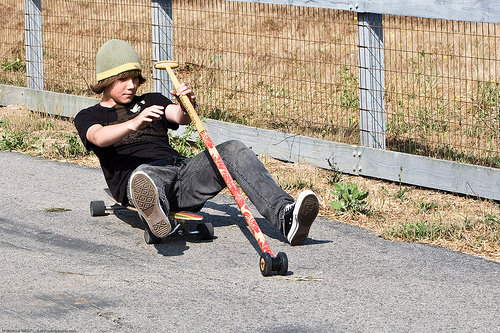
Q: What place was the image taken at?
A: It was taken at the pavement.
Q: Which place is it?
A: It is a pavement.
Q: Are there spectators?
A: No, there are no spectators.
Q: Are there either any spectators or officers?
A: No, there are no spectators or officers.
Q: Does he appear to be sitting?
A: Yes, the guy is sitting.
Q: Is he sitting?
A: Yes, the guy is sitting.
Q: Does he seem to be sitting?
A: Yes, the guy is sitting.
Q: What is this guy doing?
A: The guy is sitting.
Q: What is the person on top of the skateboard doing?
A: The guy is sitting.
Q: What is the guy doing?
A: The guy is sitting.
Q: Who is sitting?
A: The guy is sitting.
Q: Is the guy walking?
A: No, the guy is sitting.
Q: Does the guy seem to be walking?
A: No, the guy is sitting.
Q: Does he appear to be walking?
A: No, the guy is sitting.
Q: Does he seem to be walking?
A: No, the guy is sitting.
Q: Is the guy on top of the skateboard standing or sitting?
A: The guy is sitting.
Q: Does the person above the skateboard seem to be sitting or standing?
A: The guy is sitting.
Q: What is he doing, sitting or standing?
A: The guy is sitting.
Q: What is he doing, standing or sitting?
A: The guy is sitting.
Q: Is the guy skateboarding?
A: Yes, the guy is skateboarding.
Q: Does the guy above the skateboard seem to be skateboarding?
A: Yes, the guy is skateboarding.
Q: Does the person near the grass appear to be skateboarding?
A: Yes, the guy is skateboarding.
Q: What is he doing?
A: The guy is skateboarding.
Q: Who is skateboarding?
A: The guy is skateboarding.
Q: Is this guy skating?
A: No, the guy is skateboarding.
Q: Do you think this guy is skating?
A: No, the guy is skateboarding.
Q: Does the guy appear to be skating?
A: No, the guy is skateboarding.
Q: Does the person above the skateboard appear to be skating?
A: No, the guy is skateboarding.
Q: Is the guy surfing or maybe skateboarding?
A: The guy is skateboarding.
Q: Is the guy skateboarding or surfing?
A: The guy is skateboarding.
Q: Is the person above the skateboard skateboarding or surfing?
A: The guy is skateboarding.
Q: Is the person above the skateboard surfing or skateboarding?
A: The guy is skateboarding.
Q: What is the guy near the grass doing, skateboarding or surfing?
A: The guy is skateboarding.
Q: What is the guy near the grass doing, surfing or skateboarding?
A: The guy is skateboarding.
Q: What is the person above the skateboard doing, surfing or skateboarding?
A: The guy is skateboarding.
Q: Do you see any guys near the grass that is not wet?
A: Yes, there is a guy near the grass.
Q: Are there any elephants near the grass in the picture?
A: No, there is a guy near the grass.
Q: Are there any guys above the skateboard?
A: Yes, there is a guy above the skateboard.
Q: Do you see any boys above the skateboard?
A: No, there is a guy above the skateboard.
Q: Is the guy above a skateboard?
A: Yes, the guy is above a skateboard.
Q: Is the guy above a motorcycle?
A: No, the guy is above a skateboard.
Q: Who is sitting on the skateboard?
A: The guy is sitting on the skateboard.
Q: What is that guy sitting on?
A: The guy is sitting on the skateboard.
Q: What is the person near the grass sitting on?
A: The guy is sitting on the skateboard.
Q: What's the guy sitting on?
A: The guy is sitting on the skateboard.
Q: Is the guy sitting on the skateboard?
A: Yes, the guy is sitting on the skateboard.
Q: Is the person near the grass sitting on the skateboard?
A: Yes, the guy is sitting on the skateboard.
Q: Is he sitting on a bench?
A: No, the guy is sitting on the skateboard.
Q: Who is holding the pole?
A: The guy is holding the pole.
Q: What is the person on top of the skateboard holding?
A: The guy is holding the pole.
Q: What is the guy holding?
A: The guy is holding the pole.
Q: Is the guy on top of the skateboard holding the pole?
A: Yes, the guy is holding the pole.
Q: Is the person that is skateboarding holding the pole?
A: Yes, the guy is holding the pole.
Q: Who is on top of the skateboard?
A: The guy is on top of the skateboard.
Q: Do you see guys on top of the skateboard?
A: Yes, there is a guy on top of the skateboard.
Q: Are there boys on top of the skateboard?
A: No, there is a guy on top of the skateboard.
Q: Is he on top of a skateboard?
A: Yes, the guy is on top of a skateboard.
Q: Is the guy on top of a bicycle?
A: No, the guy is on top of a skateboard.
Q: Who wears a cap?
A: The guy wears a cap.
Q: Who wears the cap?
A: The guy wears a cap.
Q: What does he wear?
A: The guy wears a cap.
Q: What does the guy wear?
A: The guy wears a cap.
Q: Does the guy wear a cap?
A: Yes, the guy wears a cap.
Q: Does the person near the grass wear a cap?
A: Yes, the guy wears a cap.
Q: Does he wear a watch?
A: No, the guy wears a cap.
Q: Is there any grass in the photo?
A: Yes, there is grass.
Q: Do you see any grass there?
A: Yes, there is grass.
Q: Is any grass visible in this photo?
A: Yes, there is grass.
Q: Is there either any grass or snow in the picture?
A: Yes, there is grass.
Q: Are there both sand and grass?
A: No, there is grass but no sand.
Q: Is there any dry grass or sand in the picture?
A: Yes, there is dry grass.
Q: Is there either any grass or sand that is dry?
A: Yes, the grass is dry.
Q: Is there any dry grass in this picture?
A: Yes, there is dry grass.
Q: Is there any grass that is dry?
A: Yes, there is grass that is dry.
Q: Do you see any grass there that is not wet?
A: Yes, there is dry grass.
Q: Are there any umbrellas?
A: No, there are no umbrellas.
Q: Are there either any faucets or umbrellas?
A: No, there are no umbrellas or faucets.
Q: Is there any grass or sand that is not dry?
A: No, there is grass but it is dry.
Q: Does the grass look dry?
A: Yes, the grass is dry.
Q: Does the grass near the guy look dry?
A: Yes, the grass is dry.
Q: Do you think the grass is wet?
A: No, the grass is dry.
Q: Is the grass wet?
A: No, the grass is dry.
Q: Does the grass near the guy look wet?
A: No, the grass is dry.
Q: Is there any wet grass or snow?
A: No, there is grass but it is dry.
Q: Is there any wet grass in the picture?
A: No, there is grass but it is dry.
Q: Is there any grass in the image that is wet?
A: No, there is grass but it is dry.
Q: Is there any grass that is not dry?
A: No, there is grass but it is dry.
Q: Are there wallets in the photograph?
A: No, there are no wallets.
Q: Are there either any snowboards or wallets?
A: No, there are no wallets or snowboards.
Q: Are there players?
A: No, there are no players.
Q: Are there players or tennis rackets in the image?
A: No, there are no players or tennis rackets.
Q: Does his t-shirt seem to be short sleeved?
A: Yes, the tshirt is short sleeved.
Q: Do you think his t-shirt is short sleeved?
A: Yes, the tshirt is short sleeved.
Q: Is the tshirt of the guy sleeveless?
A: No, the tee shirt is short sleeved.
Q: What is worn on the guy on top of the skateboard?
A: The cap is worn on the guy.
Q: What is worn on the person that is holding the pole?
A: The cap is worn on the guy.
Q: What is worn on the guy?
A: The cap is worn on the guy.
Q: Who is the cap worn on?
A: The cap is worn on the guy.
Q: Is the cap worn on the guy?
A: Yes, the cap is worn on the guy.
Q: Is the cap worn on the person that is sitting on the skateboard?
A: Yes, the cap is worn on the guy.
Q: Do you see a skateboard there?
A: Yes, there is a skateboard.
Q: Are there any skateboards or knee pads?
A: Yes, there is a skateboard.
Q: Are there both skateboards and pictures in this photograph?
A: No, there is a skateboard but no pictures.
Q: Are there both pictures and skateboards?
A: No, there is a skateboard but no pictures.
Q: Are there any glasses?
A: No, there are no glasses.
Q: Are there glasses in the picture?
A: No, there are no glasses.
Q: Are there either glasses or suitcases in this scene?
A: No, there are no glasses or suitcases.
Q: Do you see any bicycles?
A: No, there are no bicycles.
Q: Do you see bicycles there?
A: No, there are no bicycles.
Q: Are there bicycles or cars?
A: No, there are no bicycles or cars.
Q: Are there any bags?
A: No, there are no bags.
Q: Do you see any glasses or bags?
A: No, there are no bags or glasses.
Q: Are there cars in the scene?
A: No, there are no cars.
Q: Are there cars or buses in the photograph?
A: No, there are no cars or buses.